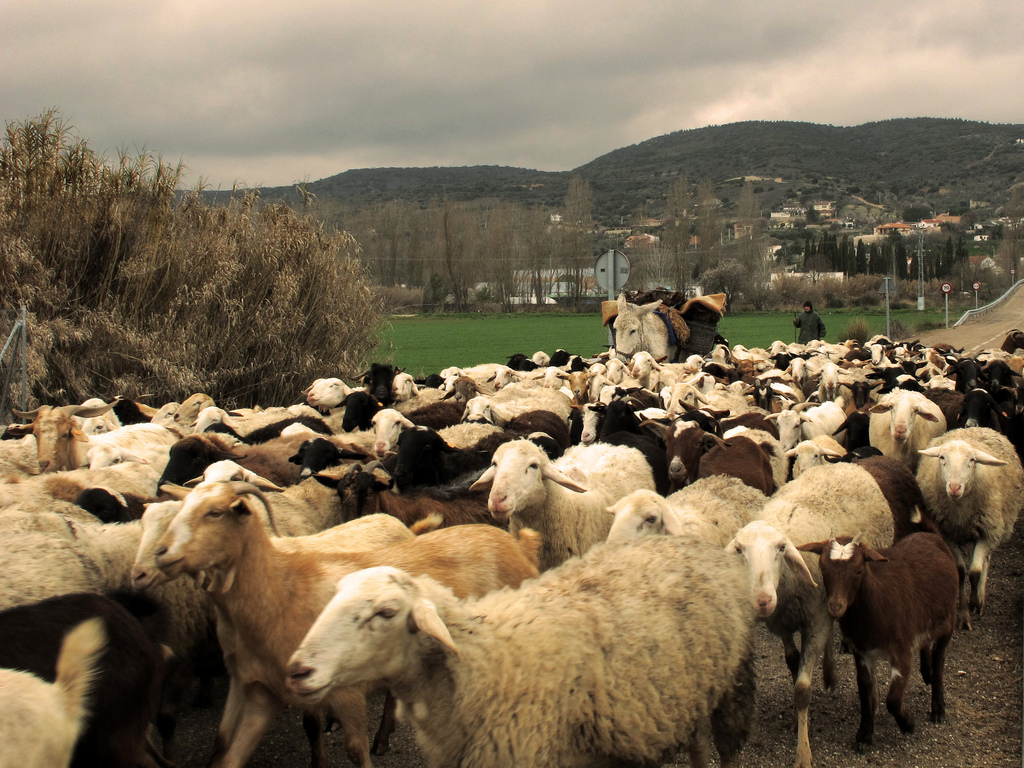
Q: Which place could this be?
A: It is a field.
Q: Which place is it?
A: It is a field.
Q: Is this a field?
A: Yes, it is a field.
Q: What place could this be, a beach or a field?
A: It is a field.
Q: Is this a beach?
A: No, it is a field.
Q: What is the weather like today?
A: It is cloudy.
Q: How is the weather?
A: It is cloudy.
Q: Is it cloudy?
A: Yes, it is cloudy.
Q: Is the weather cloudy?
A: Yes, it is cloudy.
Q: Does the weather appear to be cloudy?
A: Yes, it is cloudy.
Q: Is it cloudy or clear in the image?
A: It is cloudy.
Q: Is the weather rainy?
A: No, it is cloudy.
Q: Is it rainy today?
A: No, it is cloudy.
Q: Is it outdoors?
A: Yes, it is outdoors.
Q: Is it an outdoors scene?
A: Yes, it is outdoors.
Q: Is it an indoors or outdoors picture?
A: It is outdoors.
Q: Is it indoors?
A: No, it is outdoors.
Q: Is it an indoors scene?
A: No, it is outdoors.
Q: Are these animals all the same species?
A: No, there are both sheep and horses.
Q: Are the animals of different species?
A: Yes, they are sheep and horses.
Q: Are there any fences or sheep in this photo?
A: Yes, there is a sheep.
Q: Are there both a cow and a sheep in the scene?
A: No, there is a sheep but no cows.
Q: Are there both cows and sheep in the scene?
A: No, there is a sheep but no cows.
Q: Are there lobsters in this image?
A: No, there are no lobsters.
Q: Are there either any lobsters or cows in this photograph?
A: No, there are no lobsters or cows.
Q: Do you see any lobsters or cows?
A: No, there are no lobsters or cows.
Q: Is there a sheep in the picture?
A: Yes, there is a sheep.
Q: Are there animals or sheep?
A: Yes, there is a sheep.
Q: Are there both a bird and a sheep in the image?
A: No, there is a sheep but no birds.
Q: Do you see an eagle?
A: No, there are no eagles.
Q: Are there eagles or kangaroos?
A: No, there are no eagles or kangaroos.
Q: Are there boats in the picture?
A: No, there are no boats.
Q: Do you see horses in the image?
A: Yes, there is a horse.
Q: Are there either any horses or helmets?
A: Yes, there is a horse.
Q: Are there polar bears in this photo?
A: No, there are no polar bears.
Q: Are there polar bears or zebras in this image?
A: No, there are no polar bears or zebras.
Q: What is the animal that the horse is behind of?
A: The animal is a sheep.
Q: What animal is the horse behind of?
A: The horse is behind the sheep.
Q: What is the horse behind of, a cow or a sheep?
A: The horse is behind a sheep.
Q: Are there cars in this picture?
A: No, there are no cars.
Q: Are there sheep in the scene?
A: Yes, there is a sheep.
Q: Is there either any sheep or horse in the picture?
A: Yes, there is a sheep.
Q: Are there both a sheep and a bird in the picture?
A: No, there is a sheep but no birds.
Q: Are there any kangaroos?
A: No, there are no kangaroos.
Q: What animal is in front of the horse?
A: The sheep is in front of the horse.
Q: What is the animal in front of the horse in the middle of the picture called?
A: The animal is a sheep.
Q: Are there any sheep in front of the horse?
A: Yes, there is a sheep in front of the horse.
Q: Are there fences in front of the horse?
A: No, there is a sheep in front of the horse.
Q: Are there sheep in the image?
A: Yes, there is a sheep.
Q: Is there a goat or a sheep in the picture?
A: Yes, there is a sheep.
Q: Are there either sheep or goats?
A: Yes, there is a sheep.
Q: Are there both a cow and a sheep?
A: No, there is a sheep but no cows.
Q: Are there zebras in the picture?
A: No, there are no zebras.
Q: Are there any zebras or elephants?
A: No, there are no zebras or elephants.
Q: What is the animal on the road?
A: The animal is a sheep.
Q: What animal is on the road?
A: The animal is a sheep.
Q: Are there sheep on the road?
A: Yes, there is a sheep on the road.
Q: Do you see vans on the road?
A: No, there is a sheep on the road.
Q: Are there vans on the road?
A: No, there is a sheep on the road.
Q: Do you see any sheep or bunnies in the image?
A: Yes, there is a sheep.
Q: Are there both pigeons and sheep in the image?
A: No, there is a sheep but no pigeons.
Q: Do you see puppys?
A: No, there are no puppys.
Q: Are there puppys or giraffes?
A: No, there are no puppys or giraffes.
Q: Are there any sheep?
A: Yes, there is a sheep.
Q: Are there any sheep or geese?
A: Yes, there is a sheep.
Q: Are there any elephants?
A: No, there are no elephants.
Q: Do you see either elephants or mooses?
A: No, there are no elephants or mooses.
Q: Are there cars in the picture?
A: No, there are no cars.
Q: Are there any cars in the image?
A: No, there are no cars.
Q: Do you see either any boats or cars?
A: No, there are no cars or boats.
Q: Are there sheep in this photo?
A: Yes, there is a sheep.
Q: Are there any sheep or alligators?
A: Yes, there is a sheep.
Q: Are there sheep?
A: Yes, there is a sheep.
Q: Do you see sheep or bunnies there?
A: Yes, there is a sheep.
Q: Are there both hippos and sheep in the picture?
A: No, there is a sheep but no hippos.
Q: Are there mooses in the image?
A: No, there are no mooses.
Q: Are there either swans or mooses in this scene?
A: No, there are no mooses or swans.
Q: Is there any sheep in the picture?
A: Yes, there is a sheep.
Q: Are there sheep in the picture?
A: Yes, there is a sheep.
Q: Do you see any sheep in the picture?
A: Yes, there is a sheep.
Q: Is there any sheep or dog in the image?
A: Yes, there is a sheep.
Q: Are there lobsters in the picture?
A: No, there are no lobsters.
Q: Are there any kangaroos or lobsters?
A: No, there are no lobsters or kangaroos.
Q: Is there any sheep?
A: Yes, there is a sheep.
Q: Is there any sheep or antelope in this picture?
A: Yes, there is a sheep.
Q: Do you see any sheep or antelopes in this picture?
A: Yes, there is a sheep.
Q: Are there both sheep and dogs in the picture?
A: No, there is a sheep but no dogs.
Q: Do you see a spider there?
A: No, there are no spiders.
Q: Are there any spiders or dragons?
A: No, there are no spiders or dragons.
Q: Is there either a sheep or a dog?
A: Yes, there is a sheep.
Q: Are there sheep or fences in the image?
A: Yes, there is a sheep.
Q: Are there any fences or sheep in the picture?
A: Yes, there is a sheep.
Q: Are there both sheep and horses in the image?
A: Yes, there are both a sheep and horses.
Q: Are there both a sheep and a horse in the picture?
A: Yes, there are both a sheep and a horse.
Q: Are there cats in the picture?
A: No, there are no cats.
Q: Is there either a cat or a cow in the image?
A: No, there are no cats or cows.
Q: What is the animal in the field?
A: The animal is a sheep.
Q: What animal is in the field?
A: The animal is a sheep.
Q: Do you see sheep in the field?
A: Yes, there is a sheep in the field.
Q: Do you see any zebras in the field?
A: No, there is a sheep in the field.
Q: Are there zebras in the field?
A: No, there is a sheep in the field.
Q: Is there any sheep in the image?
A: Yes, there is a sheep.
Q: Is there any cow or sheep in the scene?
A: Yes, there is a sheep.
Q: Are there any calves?
A: No, there are no calves.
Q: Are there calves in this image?
A: No, there are no calves.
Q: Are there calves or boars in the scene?
A: No, there are no calves or boars.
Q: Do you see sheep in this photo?
A: Yes, there is a sheep.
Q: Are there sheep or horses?
A: Yes, there is a sheep.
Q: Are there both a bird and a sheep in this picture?
A: No, there is a sheep but no birds.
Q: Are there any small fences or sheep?
A: Yes, there is a small sheep.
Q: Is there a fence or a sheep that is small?
A: Yes, the sheep is small.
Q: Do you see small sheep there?
A: Yes, there is a small sheep.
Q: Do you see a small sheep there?
A: Yes, there is a small sheep.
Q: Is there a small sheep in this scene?
A: Yes, there is a small sheep.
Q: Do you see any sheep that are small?
A: Yes, there is a small sheep.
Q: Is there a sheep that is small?
A: Yes, there is a sheep that is small.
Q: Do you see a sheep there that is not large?
A: Yes, there is a small sheep.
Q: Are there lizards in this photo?
A: No, there are no lizards.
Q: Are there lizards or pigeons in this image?
A: No, there are no lizards or pigeons.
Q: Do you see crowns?
A: No, there are no crowns.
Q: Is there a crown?
A: No, there are no crowns.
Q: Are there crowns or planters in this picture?
A: No, there are no crowns or planters.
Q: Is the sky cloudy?
A: Yes, the sky is cloudy.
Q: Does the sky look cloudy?
A: Yes, the sky is cloudy.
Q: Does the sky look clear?
A: No, the sky is cloudy.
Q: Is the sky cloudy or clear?
A: The sky is cloudy.